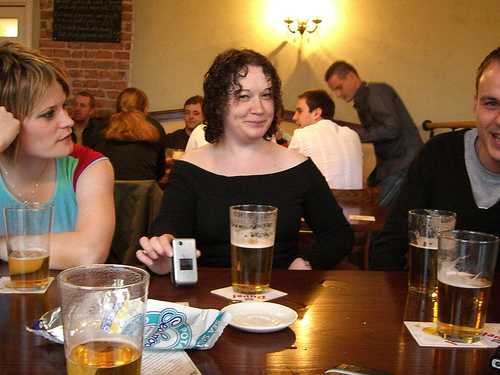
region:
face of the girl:
[191, 36, 303, 141]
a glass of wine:
[42, 250, 177, 372]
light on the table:
[268, 290, 340, 366]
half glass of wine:
[71, 349, 150, 374]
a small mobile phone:
[154, 230, 219, 295]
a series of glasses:
[415, 218, 498, 343]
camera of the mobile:
[173, 233, 188, 250]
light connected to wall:
[257, 11, 406, 61]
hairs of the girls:
[195, 58, 237, 150]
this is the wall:
[152, 10, 192, 67]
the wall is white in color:
[406, 32, 427, 52]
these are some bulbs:
[255, 2, 345, 44]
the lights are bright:
[261, 5, 343, 42]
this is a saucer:
[221, 296, 301, 338]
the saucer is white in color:
[249, 307, 270, 322]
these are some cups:
[6, 194, 487, 374]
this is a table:
[331, 261, 399, 330]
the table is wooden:
[323, 308, 366, 354]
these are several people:
[17, 48, 499, 216]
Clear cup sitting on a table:
[223, 184, 281, 301]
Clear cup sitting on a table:
[387, 192, 445, 309]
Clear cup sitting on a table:
[435, 215, 495, 353]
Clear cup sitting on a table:
[37, 252, 207, 372]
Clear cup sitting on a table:
[7, 189, 50, 277]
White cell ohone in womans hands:
[145, 212, 205, 295]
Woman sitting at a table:
[175, 37, 362, 284]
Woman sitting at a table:
[1, 25, 123, 303]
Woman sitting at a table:
[97, 75, 167, 195]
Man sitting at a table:
[395, 15, 498, 204]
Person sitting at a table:
[180, 20, 376, 298]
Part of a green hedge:
[5, 33, 127, 306]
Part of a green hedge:
[292, 77, 364, 202]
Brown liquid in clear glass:
[218, 177, 283, 307]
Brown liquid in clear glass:
[388, 196, 446, 308]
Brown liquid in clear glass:
[437, 221, 487, 368]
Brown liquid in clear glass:
[42, 252, 165, 370]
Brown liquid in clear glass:
[3, 198, 56, 311]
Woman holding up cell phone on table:
[134, 47, 356, 286]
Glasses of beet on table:
[406, 207, 498, 344]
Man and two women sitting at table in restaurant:
[2, 41, 498, 271]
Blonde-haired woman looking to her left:
[0, 34, 117, 271]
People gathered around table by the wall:
[68, 57, 423, 249]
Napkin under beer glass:
[211, 277, 288, 302]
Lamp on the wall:
[281, 0, 321, 62]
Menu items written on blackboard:
[49, 0, 126, 43]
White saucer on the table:
[221, 298, 298, 335]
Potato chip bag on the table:
[25, 289, 230, 353]